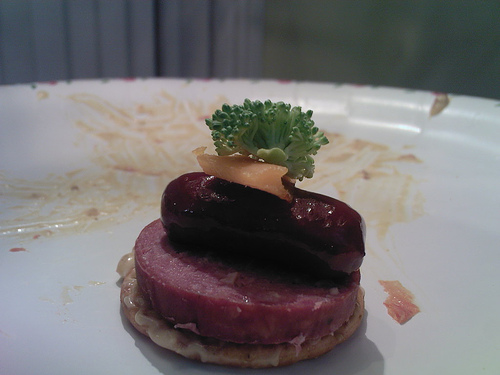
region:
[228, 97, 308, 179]
green broccoli on plate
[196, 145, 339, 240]
small slice of cheese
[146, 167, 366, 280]
dark red meat on plate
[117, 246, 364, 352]
white cracker on plate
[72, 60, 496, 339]
large and white plate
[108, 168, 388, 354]
small hors d'oeuvre on plate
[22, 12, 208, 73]
white blinds behind plate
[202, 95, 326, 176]
small and uncooked broccoli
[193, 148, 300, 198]
the yellow cheese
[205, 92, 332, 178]
the green vegetable on top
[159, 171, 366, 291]
the rolled up sausage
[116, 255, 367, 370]
a brown crispy cracker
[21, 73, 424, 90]
the design on edge of plate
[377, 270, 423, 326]
the red sauce on plate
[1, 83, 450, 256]
the after sauce on plate from food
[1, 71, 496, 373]
a plate of food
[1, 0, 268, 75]
the hanging blinds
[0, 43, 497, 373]
this is a plate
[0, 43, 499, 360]
the plate is white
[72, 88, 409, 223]
brown stain on plate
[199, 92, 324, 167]
a sprig of broccoli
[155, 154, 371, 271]
a small brown sausage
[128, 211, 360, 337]
a slice of meat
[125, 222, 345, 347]
the slice of meat is pink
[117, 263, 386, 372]
cracker under the meat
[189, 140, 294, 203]
a small piece of cheese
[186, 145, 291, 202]
the cheese is yellow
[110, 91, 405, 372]
This is a sandwich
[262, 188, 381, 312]
This is a sandwich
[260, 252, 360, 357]
Section of a sandwich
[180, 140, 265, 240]
Section of a sandwich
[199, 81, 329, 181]
a piece of broccoli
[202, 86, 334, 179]
the broccoli is green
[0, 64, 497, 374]
food in a white dish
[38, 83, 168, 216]
stains on the dish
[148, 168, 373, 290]
a ham color red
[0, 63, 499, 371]
the dish is color white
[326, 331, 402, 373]
the shadow cast on the dish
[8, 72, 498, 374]
white plate on the table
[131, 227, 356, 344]
pink meat on the cracker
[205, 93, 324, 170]
broccoli on the cheese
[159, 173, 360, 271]
mini hot dog on the meat slice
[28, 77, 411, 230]
smear of sauce on the plate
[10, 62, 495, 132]
rim of the plate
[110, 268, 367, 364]
cracker on the plate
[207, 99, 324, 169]
green sprigy broccoli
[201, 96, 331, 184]
small piece of raw broccoli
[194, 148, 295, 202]
sliver of honey dew melon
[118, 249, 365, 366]
round wheat cracker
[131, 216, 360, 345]
round slice of sausage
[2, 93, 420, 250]
orange sauce smeared on a plate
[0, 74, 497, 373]
white paper plate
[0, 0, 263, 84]
white vertical window blinds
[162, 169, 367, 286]
small whole sausage covered in BBQ sauce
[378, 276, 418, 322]
small piece of melon